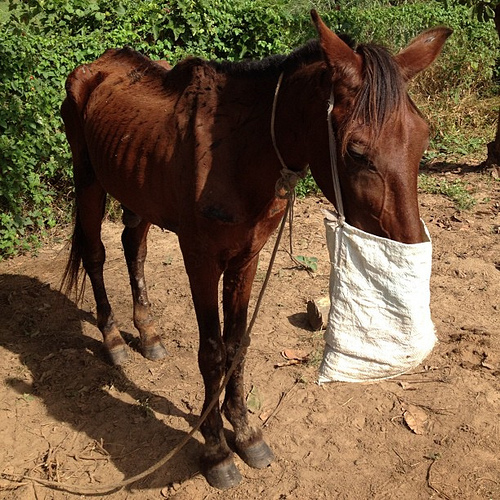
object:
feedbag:
[316, 205, 439, 389]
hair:
[337, 38, 412, 162]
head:
[305, 8, 456, 245]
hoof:
[142, 340, 169, 361]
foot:
[138, 323, 168, 360]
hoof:
[106, 349, 129, 366]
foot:
[99, 329, 131, 368]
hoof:
[238, 439, 275, 469]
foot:
[236, 426, 275, 471]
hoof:
[208, 464, 245, 490]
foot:
[202, 440, 243, 492]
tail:
[53, 93, 91, 312]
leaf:
[40, 70, 57, 81]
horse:
[60, 6, 457, 491]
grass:
[418, 108, 500, 211]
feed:
[330, 231, 428, 363]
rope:
[0, 65, 311, 495]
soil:
[0, 148, 499, 499]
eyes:
[343, 141, 372, 167]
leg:
[72, 189, 131, 361]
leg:
[120, 206, 169, 361]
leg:
[178, 236, 242, 488]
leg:
[221, 250, 276, 470]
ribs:
[135, 120, 158, 222]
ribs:
[149, 123, 169, 223]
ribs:
[122, 121, 146, 204]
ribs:
[159, 135, 175, 227]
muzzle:
[334, 222, 429, 303]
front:
[306, 19, 456, 379]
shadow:
[0, 272, 245, 497]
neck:
[255, 58, 318, 175]